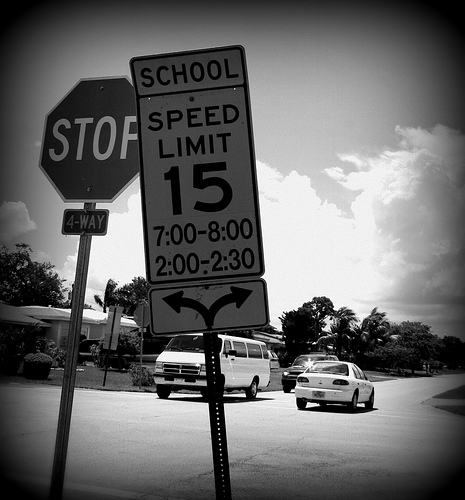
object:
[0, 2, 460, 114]
sky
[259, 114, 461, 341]
clouds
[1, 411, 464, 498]
road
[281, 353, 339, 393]
truck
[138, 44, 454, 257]
sky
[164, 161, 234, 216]
15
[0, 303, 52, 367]
house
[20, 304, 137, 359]
house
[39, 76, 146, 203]
stop sign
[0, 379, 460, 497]
intersection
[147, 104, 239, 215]
limit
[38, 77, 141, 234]
sign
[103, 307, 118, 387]
pole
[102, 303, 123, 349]
sign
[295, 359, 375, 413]
white car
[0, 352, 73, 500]
corner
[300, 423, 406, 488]
ground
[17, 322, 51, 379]
bush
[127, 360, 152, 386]
bush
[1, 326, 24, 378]
bush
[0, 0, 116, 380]
corner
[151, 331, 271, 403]
cars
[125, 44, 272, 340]
sign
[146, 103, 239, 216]
speed limit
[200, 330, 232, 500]
pole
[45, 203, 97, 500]
pole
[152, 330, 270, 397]
van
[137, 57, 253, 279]
letters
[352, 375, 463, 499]
road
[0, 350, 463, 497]
road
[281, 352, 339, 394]
car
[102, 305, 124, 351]
post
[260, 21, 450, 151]
part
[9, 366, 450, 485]
tarmac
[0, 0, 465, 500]
photo